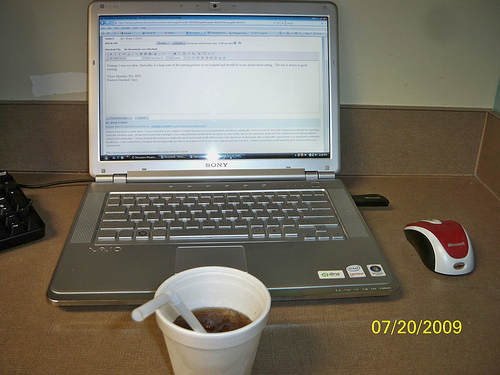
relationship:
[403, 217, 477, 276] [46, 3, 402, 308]
mouse next to computer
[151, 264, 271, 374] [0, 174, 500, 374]
cup on top of table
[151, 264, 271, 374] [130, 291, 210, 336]
cup has straw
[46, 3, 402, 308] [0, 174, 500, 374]
computer on top of desk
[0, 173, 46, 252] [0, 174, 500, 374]
keyboard on top of table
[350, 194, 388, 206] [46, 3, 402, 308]
usb drive in computer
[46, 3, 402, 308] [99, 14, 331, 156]
computer has screen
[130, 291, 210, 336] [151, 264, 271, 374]
straw inside cup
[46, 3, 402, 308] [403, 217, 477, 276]
computer has mouse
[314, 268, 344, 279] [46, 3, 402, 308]
sticker on computer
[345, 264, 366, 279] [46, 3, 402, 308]
sticker on computer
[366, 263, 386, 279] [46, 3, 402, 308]
sticker on computer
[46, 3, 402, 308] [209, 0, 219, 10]
computer has webcam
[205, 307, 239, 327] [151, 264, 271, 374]
ice inside cup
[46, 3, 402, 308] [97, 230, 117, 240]
computer has button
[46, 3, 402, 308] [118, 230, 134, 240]
computer has button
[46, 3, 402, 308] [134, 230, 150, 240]
computer has button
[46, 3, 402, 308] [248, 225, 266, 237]
computer has button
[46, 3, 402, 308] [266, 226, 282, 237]
computer has button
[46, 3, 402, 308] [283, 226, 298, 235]
computer has button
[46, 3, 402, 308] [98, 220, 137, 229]
computer has button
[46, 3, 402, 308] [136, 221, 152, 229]
computer has button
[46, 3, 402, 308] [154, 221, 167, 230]
computer has button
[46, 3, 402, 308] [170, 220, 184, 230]
computer has button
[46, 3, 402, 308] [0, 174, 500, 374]
computer on top of table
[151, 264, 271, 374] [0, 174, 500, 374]
cup o top of table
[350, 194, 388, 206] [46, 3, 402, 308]
usb drive connected to computer